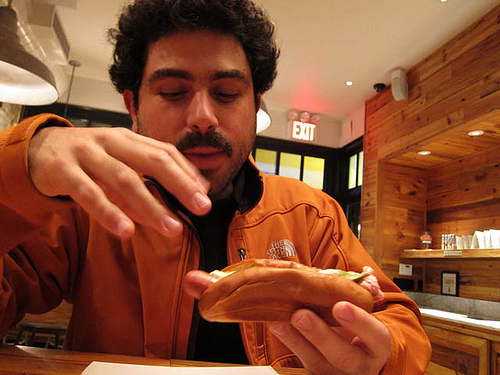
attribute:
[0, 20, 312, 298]
man — holding dog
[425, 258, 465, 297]
frame — black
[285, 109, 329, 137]
sign — exit, emergency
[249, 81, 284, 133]
light — hanging, round, white, silver, ceiling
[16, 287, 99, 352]
stool — top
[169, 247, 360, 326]
dog — sandwich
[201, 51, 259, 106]
eye — black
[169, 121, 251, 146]
mustached — black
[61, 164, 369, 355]
jacket — orange, brown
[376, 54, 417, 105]
speaker — grey, white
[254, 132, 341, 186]
window — large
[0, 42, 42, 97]
lamp — shade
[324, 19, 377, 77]
ceiling — white